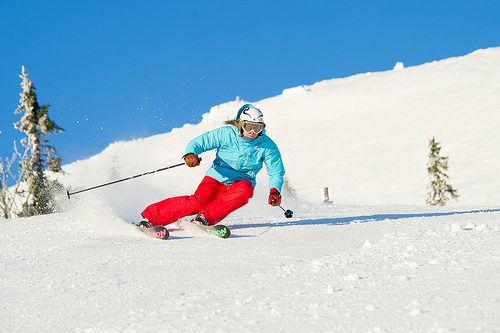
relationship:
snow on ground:
[2, 237, 491, 324] [1, 46, 497, 329]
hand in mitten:
[179, 151, 202, 168] [181, 148, 206, 168]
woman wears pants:
[69, 104, 296, 239] [139, 175, 257, 228]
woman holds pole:
[69, 104, 296, 239] [65, 153, 205, 201]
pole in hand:
[65, 153, 205, 201] [179, 151, 202, 168]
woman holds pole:
[69, 104, 296, 239] [268, 197, 296, 220]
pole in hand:
[268, 197, 296, 220] [266, 188, 284, 207]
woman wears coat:
[69, 104, 296, 239] [186, 125, 283, 196]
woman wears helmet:
[69, 104, 296, 239] [235, 106, 268, 144]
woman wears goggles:
[69, 104, 296, 239] [236, 117, 266, 138]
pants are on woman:
[139, 175, 257, 228] [69, 104, 296, 239]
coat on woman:
[184, 123, 287, 200] [138, 105, 286, 231]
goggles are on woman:
[236, 117, 266, 138] [69, 104, 296, 239]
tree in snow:
[422, 138, 461, 210] [1, 46, 497, 329]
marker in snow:
[318, 183, 337, 207] [1, 46, 497, 329]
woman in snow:
[138, 105, 286, 231] [1, 46, 497, 329]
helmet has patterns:
[235, 106, 268, 144] [233, 104, 268, 123]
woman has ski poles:
[138, 105, 286, 231] [62, 154, 298, 220]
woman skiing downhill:
[138, 105, 286, 231] [1, 46, 497, 329]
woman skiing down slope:
[69, 104, 296, 239] [1, 46, 497, 329]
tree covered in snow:
[1, 63, 86, 219] [1, 46, 497, 329]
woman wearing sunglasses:
[69, 104, 296, 239] [236, 117, 266, 138]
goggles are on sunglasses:
[237, 119, 266, 135] [236, 117, 266, 138]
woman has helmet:
[138, 105, 286, 231] [235, 106, 268, 144]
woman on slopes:
[69, 104, 296, 239] [1, 46, 497, 329]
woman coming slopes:
[69, 104, 296, 239] [1, 46, 497, 329]